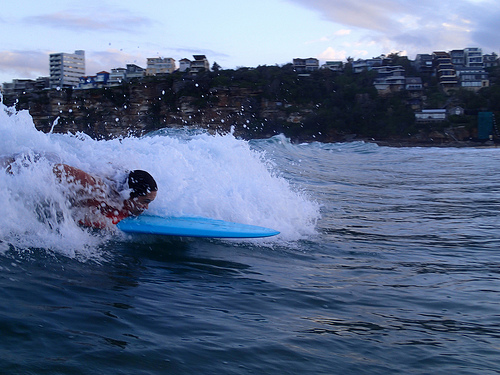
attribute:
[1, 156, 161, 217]
surfer — swimming, surfing, face down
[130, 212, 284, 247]
surfboard — blue, red painted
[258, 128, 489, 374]
water — blue, ocean, large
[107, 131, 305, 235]
waves — crashing, splashing, small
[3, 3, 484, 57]
skies — blue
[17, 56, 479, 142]
city — urban